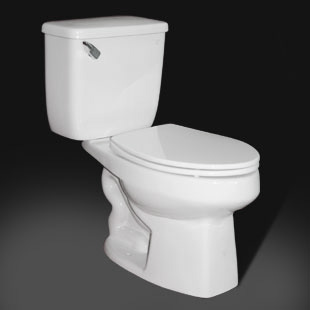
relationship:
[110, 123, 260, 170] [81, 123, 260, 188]
protective pad on bottom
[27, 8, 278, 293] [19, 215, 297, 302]
white toilet on floor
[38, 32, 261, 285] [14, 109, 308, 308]
toilet on floor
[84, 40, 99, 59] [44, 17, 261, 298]
handle flush toilet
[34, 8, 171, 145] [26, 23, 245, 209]
tank behind toilet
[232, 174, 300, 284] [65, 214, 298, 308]
shadow on ground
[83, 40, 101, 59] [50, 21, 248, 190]
handle on toilet